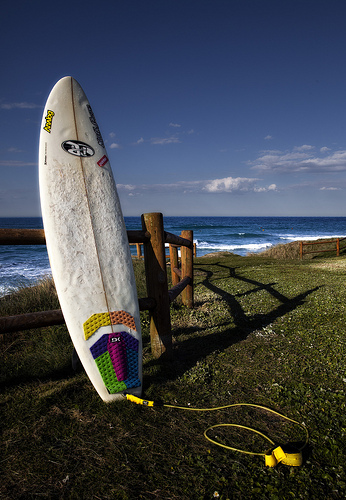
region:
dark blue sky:
[156, 42, 184, 57]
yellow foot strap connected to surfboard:
[127, 394, 308, 468]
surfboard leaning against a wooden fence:
[37, 73, 143, 403]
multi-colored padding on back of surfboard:
[83, 310, 141, 395]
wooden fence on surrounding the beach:
[0, 211, 194, 359]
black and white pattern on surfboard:
[60, 139, 94, 157]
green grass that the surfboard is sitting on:
[47, 407, 113, 438]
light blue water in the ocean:
[210, 218, 253, 227]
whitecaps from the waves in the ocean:
[192, 237, 271, 250]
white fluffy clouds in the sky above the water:
[113, 176, 276, 196]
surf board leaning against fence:
[35, 74, 150, 409]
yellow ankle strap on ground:
[201, 417, 313, 474]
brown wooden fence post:
[136, 209, 198, 368]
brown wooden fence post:
[177, 227, 203, 310]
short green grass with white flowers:
[221, 280, 281, 335]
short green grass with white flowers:
[250, 336, 299, 382]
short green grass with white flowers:
[261, 263, 299, 322]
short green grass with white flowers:
[72, 424, 132, 452]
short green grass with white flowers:
[187, 454, 226, 488]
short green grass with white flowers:
[217, 267, 253, 315]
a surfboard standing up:
[16, 55, 142, 440]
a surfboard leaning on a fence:
[22, 35, 225, 433]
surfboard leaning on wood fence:
[20, 42, 241, 429]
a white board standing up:
[2, 49, 234, 434]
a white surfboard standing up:
[25, 50, 245, 436]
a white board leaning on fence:
[27, 39, 171, 430]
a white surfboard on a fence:
[25, 73, 237, 467]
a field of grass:
[195, 294, 340, 432]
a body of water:
[202, 215, 235, 240]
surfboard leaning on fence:
[32, 72, 153, 416]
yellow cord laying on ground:
[127, 394, 320, 467]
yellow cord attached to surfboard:
[116, 390, 319, 470]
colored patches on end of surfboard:
[80, 305, 145, 395]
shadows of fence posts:
[194, 262, 314, 361]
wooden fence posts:
[139, 210, 228, 371]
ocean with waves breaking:
[197, 210, 279, 253]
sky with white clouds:
[190, 137, 339, 212]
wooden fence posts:
[297, 233, 345, 261]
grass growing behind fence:
[7, 270, 56, 366]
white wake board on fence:
[33, 77, 158, 418]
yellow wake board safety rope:
[119, 381, 316, 467]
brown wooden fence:
[140, 210, 200, 358]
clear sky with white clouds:
[195, 122, 345, 213]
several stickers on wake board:
[43, 112, 109, 181]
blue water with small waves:
[201, 223, 256, 253]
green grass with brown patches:
[39, 398, 100, 454]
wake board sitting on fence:
[0, 89, 207, 407]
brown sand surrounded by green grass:
[319, 255, 345, 276]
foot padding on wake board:
[81, 308, 143, 397]